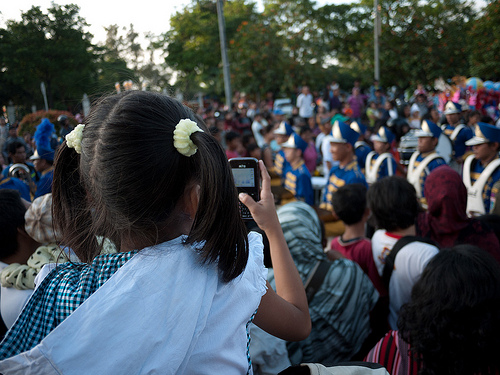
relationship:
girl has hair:
[0, 88, 313, 373] [51, 88, 249, 284]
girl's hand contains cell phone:
[234, 156, 281, 236] [227, 153, 264, 225]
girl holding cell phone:
[0, 88, 313, 373] [228, 151, 263, 218]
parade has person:
[2, 119, 499, 219] [329, 182, 371, 271]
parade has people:
[2, 119, 499, 219] [367, 175, 438, 330]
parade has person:
[2, 119, 499, 219] [416, 168, 472, 245]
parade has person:
[2, 119, 499, 219] [348, 82, 367, 115]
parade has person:
[2, 119, 499, 219] [411, 92, 429, 115]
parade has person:
[2, 119, 499, 219] [296, 85, 315, 120]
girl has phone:
[0, 88, 313, 373] [223, 152, 261, 224]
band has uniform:
[222, 100, 499, 220] [465, 124, 499, 216]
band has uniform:
[222, 100, 499, 220] [364, 122, 448, 203]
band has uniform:
[222, 100, 499, 220] [320, 122, 366, 210]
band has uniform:
[222, 100, 499, 220] [28, 120, 59, 192]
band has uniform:
[1, 119, 60, 208] [465, 124, 499, 216]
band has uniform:
[1, 119, 60, 208] [364, 122, 448, 203]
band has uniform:
[1, 119, 60, 208] [320, 122, 366, 210]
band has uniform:
[1, 119, 60, 208] [28, 120, 59, 192]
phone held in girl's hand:
[224, 157, 264, 222] [237, 159, 279, 230]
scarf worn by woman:
[274, 202, 380, 337] [265, 201, 390, 373]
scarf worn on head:
[274, 202, 380, 337] [272, 201, 322, 264]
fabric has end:
[5, 227, 274, 373] [242, 306, 258, 373]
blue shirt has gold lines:
[320, 165, 361, 217] [330, 175, 345, 193]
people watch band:
[335, 166, 467, 311] [269, 111, 498, 215]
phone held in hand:
[224, 157, 264, 222] [232, 158, 284, 235]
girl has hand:
[0, 88, 313, 373] [232, 158, 284, 235]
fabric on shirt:
[0, 227, 266, 375] [1, 230, 269, 372]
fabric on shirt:
[0, 227, 266, 375] [20, 257, 132, 344]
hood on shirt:
[1, 247, 208, 374] [0, 230, 272, 375]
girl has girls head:
[0, 88, 313, 373] [74, 88, 202, 242]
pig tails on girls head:
[185, 135, 247, 282] [74, 88, 202, 242]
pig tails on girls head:
[55, 135, 95, 263] [74, 88, 202, 242]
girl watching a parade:
[0, 88, 313, 373] [2, 100, 497, 218]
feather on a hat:
[33, 116, 56, 166] [28, 135, 61, 161]